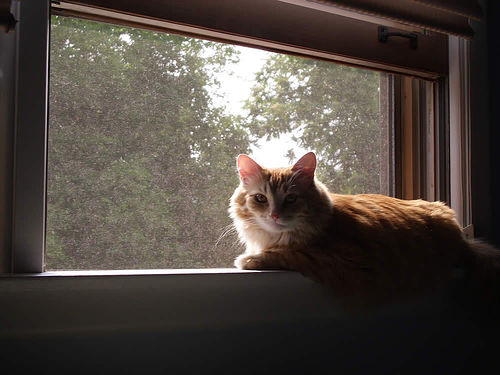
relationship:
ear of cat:
[289, 149, 320, 176] [219, 150, 498, 299]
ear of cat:
[231, 152, 266, 181] [219, 150, 498, 299]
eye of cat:
[282, 190, 301, 208] [219, 150, 498, 299]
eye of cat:
[253, 191, 269, 206] [219, 150, 498, 299]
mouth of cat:
[266, 221, 290, 232] [219, 150, 498, 299]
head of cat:
[226, 147, 330, 239] [219, 150, 498, 299]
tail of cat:
[460, 236, 500, 271] [219, 150, 498, 299]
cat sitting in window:
[219, 150, 498, 299] [9, 2, 464, 291]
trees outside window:
[40, 11, 390, 275] [9, 2, 464, 291]